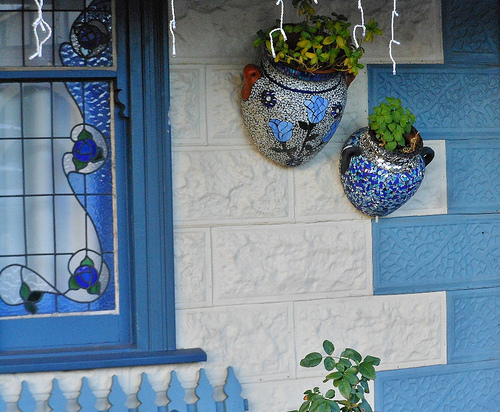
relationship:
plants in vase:
[287, 6, 386, 75] [250, 54, 340, 162]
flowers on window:
[68, 125, 109, 186] [12, 9, 131, 270]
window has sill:
[12, 9, 131, 270] [116, 24, 154, 325]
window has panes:
[12, 9, 131, 270] [4, 59, 148, 124]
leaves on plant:
[305, 24, 345, 44] [275, 17, 393, 80]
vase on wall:
[250, 54, 340, 162] [178, 25, 475, 300]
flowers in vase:
[68, 125, 109, 186] [250, 54, 340, 162]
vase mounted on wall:
[250, 54, 340, 162] [178, 25, 475, 300]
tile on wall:
[387, 67, 489, 133] [178, 25, 475, 300]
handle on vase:
[241, 62, 263, 95] [250, 54, 340, 162]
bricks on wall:
[187, 141, 314, 267] [178, 25, 475, 300]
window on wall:
[12, 9, 131, 270] [178, 25, 475, 300]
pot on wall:
[345, 151, 444, 231] [178, 25, 475, 300]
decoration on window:
[13, 42, 115, 214] [12, 9, 131, 270]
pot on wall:
[333, 129, 436, 222] [178, 25, 475, 300]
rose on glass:
[70, 244, 112, 300] [21, 127, 120, 287]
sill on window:
[116, 24, 154, 325] [12, 9, 131, 270]